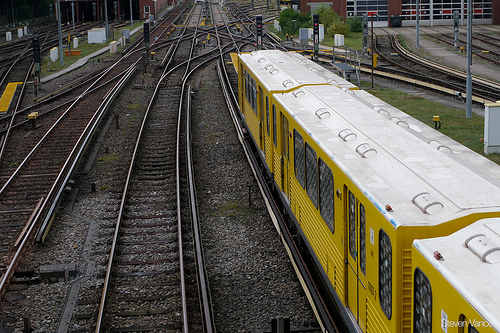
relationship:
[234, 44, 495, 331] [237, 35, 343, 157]
train with car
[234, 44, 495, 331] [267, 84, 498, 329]
train with car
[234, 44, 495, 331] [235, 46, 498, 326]
train has roof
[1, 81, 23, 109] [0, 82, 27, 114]
paint on walkway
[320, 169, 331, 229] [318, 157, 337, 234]
paint on window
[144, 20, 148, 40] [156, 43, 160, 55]
junction box for switch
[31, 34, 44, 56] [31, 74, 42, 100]
junction box for switch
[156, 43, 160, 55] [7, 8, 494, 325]
switch on rails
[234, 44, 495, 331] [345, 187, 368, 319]
train has doors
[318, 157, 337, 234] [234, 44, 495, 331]
window on train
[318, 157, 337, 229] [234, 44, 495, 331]
window on train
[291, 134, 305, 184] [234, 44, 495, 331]
window on train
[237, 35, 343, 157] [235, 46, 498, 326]
car has roof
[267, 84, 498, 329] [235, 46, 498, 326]
car has roof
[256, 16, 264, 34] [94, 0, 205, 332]
lights on railroad tracks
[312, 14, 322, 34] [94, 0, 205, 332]
lights on railroad tracks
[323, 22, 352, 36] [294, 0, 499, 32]
bush front of building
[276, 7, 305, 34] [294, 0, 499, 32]
bush front of building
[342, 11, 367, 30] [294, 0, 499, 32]
bush front of building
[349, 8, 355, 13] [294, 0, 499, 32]
window on building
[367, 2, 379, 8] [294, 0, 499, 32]
window on building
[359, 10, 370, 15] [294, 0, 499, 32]
window on building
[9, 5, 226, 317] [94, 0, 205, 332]
gravel on railroad tracks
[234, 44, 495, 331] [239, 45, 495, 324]
train has top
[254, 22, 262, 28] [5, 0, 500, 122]
light in distance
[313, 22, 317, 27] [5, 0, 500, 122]
light in distance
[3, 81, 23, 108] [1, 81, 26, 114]
strip on cement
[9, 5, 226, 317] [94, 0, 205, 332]
gravel between railroad tracks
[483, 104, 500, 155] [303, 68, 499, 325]
box in corner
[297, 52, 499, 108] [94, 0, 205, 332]
slat part of railroad tracks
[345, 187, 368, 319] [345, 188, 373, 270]
doors with windows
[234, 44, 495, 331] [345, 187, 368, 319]
train has door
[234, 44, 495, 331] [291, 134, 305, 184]
train has window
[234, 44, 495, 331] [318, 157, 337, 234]
train has window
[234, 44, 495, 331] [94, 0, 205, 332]
train on railroad tracks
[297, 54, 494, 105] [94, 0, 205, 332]
slat on railroad tracks